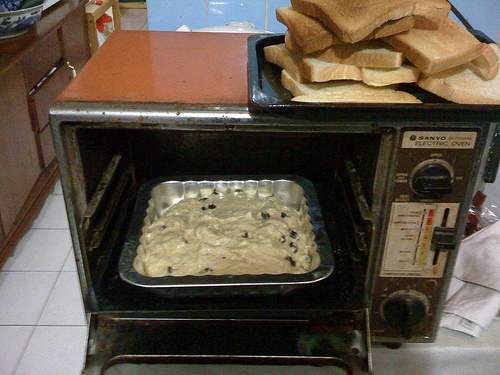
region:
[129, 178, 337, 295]
Mashed potatoes in an oven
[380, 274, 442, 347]
Knob on a microwave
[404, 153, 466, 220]
Dial on a microwave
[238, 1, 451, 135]
Bread on a pan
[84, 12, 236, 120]
Orange top on a microwave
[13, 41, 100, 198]
Brown drawers in a kitchen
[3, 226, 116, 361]
White tile on a floor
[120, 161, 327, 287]
Silver pan in a microwave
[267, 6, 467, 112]
Pile of white bread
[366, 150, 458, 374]
Controls on a microwave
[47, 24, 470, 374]
a really old toaster oven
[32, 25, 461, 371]
a dirty brown toaster oven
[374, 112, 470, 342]
the dirty oven controls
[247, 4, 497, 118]
a tray of white toast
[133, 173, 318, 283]
a square metal pan of food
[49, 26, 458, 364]
a toaster oven that should be thrown away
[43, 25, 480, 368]
who chooses these photos?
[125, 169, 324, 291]
something cooking in a dirty oven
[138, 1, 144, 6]
a cockroach in the distance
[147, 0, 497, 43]
a blue tile backsplash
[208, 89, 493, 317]
an oven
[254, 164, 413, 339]
an oven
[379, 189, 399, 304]
an oven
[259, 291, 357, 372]
an oven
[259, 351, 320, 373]
an oven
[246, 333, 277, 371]
an oven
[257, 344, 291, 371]
an oven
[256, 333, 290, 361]
an oven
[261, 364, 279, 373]
an oven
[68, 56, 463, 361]
the microwave is old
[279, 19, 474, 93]
the slices are piled up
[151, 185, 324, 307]
the pan is silver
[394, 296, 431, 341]
the knobs are black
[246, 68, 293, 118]
the tray is black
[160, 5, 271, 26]
the wall is blue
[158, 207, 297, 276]
the dough mix is wet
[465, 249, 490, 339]
the napkin is white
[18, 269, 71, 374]
the floor is tiled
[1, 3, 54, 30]
the utensil is on the counter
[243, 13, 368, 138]
toasted breads are visible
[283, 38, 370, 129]
toasted breads are visible